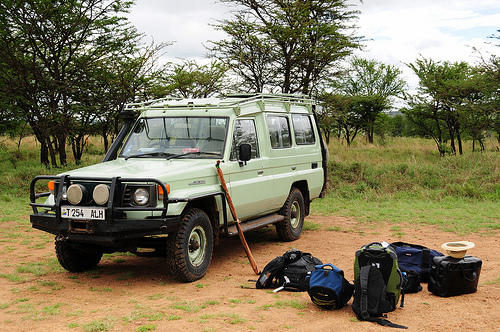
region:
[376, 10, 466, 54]
a blue sky is cloudy.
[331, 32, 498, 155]
the trees are small and green.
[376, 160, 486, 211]
the grass is short and green.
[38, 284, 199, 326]
a ground with dirt and grass.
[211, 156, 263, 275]
a long orange umbrella.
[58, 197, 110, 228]
the plate on the car says T 254 ALH.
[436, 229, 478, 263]
a round beige hat.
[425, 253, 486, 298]
a black luggage bag.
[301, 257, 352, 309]
a black and blue back pack.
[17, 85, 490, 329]
a green jeep is parked with luggage on the ground.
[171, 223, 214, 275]
front tire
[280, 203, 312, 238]
the back tire on the jeep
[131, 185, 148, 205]
the headlight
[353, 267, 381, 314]
a black and grey backpack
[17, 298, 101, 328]
patches of grass in the dirt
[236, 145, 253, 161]
a mirror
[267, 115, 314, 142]
the side windows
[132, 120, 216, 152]
the front windshield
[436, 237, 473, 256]
a helmet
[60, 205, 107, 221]
a license plate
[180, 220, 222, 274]
front tire of the jeep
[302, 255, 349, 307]
a bag on the ground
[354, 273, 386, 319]
a backpack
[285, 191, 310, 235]
back tire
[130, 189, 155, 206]
the headlight on the jeep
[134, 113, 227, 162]
the windshield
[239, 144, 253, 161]
a side mirror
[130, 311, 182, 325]
patches of dirt on the ground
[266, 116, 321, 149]
windows on the jeep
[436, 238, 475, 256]
a hat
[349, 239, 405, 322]
green and black backpack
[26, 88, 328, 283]
light green jeep idling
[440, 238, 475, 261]
vanilla hat on top of a black bag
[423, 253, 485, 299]
black bag with a hat on top of it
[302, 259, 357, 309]
blue backpack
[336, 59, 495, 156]
green trees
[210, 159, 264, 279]
brown stick leaning against the jeep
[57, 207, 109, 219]
license plate that reads "T254 ALH"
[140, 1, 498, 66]
clear sky during the day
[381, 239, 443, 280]
blue bag on the ground